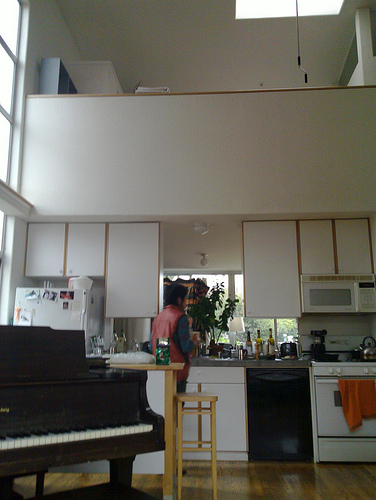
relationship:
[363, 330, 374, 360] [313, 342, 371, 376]
kettle on stove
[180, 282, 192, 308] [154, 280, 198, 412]
face of person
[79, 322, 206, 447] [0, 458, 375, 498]
table on floor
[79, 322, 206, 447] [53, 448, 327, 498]
table on floor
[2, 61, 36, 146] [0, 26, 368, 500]
window in room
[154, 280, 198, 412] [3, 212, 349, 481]
person in kitchen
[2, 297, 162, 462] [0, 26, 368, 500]
piano in room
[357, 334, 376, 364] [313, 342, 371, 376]
kettle on stove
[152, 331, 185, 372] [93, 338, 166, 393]
bottle on counter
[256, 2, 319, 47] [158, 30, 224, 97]
light on ceiling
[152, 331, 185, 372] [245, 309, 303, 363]
bottle near window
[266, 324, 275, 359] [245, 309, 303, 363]
bottle near window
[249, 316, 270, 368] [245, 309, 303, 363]
bottle near window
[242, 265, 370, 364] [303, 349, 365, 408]
microwave above a stove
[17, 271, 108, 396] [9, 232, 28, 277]
fridge near a wall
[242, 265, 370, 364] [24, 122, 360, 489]
microwave in a kitchen